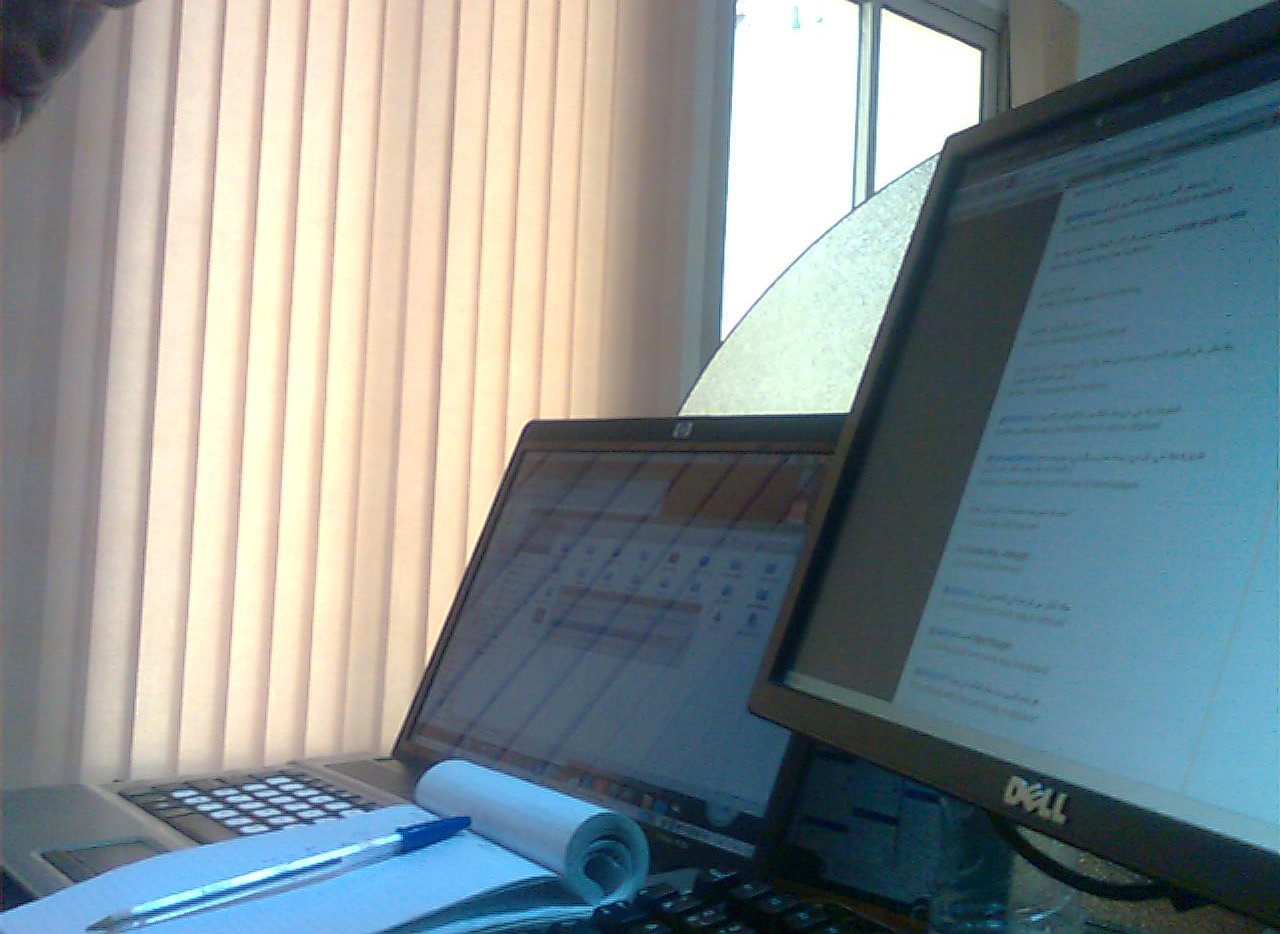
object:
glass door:
[713, 0, 993, 361]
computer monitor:
[762, 10, 1276, 921]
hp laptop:
[4, 412, 894, 916]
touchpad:
[33, 836, 159, 883]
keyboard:
[116, 736, 382, 860]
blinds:
[0, 0, 756, 787]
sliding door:
[4, 1, 993, 780]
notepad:
[4, 753, 646, 928]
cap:
[394, 810, 473, 852]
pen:
[83, 809, 479, 927]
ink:
[130, 871, 226, 931]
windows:
[703, 6, 992, 454]